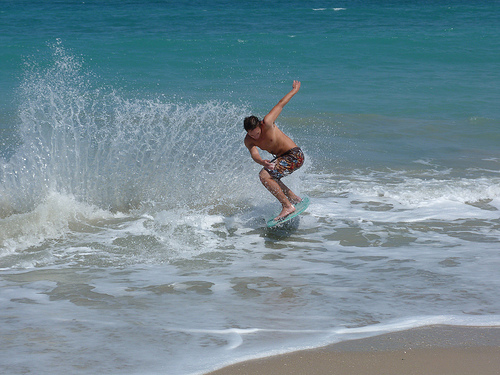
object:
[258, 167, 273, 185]
knee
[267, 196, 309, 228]
board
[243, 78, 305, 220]
man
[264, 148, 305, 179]
colorful trunks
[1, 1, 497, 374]
ocean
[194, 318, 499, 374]
edge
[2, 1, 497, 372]
water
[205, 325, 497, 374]
sand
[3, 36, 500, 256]
wave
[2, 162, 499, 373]
seafoam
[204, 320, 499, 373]
beach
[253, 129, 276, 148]
chest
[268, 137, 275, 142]
nipple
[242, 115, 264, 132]
hair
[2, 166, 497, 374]
shallow water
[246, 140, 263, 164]
arms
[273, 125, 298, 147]
back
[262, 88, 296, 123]
arm